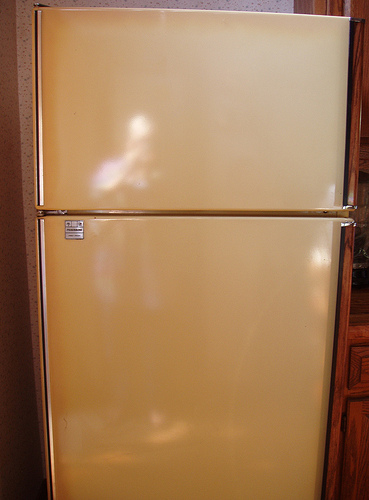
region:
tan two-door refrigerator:
[16, 7, 354, 488]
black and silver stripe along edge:
[29, 6, 57, 485]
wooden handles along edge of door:
[308, 11, 363, 488]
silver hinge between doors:
[27, 201, 72, 215]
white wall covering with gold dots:
[3, 3, 53, 303]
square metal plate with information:
[54, 213, 91, 242]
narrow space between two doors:
[29, 195, 361, 232]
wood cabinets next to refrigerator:
[335, 144, 363, 488]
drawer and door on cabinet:
[331, 333, 363, 491]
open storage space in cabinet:
[347, 109, 365, 324]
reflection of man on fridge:
[69, 99, 231, 494]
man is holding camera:
[78, 75, 186, 226]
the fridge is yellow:
[30, 10, 355, 496]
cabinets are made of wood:
[318, 0, 368, 496]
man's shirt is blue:
[89, 151, 155, 308]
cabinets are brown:
[299, 0, 367, 498]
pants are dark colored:
[94, 294, 178, 398]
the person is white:
[81, 92, 152, 194]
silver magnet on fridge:
[56, 217, 95, 251]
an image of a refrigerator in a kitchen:
[0, 0, 367, 499]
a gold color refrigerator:
[34, 4, 360, 499]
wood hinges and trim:
[346, 15, 367, 221]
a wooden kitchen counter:
[349, 253, 367, 326]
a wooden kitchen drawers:
[339, 325, 367, 498]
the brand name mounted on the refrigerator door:
[64, 220, 84, 241]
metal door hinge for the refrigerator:
[32, 0, 49, 8]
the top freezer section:
[31, 5, 364, 213]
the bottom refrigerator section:
[37, 212, 354, 498]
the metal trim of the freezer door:
[34, 8, 45, 205]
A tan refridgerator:
[20, 5, 334, 498]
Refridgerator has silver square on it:
[49, 211, 115, 267]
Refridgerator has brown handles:
[326, 25, 367, 491]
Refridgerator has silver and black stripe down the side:
[22, 4, 122, 499]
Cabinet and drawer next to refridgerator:
[326, 297, 368, 488]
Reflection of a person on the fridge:
[77, 97, 205, 456]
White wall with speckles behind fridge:
[2, 1, 298, 491]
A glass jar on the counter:
[352, 249, 368, 299]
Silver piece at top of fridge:
[23, 0, 59, 20]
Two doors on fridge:
[31, 0, 324, 487]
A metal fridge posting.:
[63, 220, 85, 239]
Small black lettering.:
[66, 225, 83, 233]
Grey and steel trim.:
[37, 218, 58, 498]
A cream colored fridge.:
[33, 4, 326, 498]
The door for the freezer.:
[39, 6, 363, 209]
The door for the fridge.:
[37, 214, 331, 499]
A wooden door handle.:
[326, 218, 357, 499]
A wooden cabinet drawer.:
[348, 346, 367, 390]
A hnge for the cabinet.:
[340, 413, 347, 437]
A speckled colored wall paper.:
[1, 8, 24, 439]